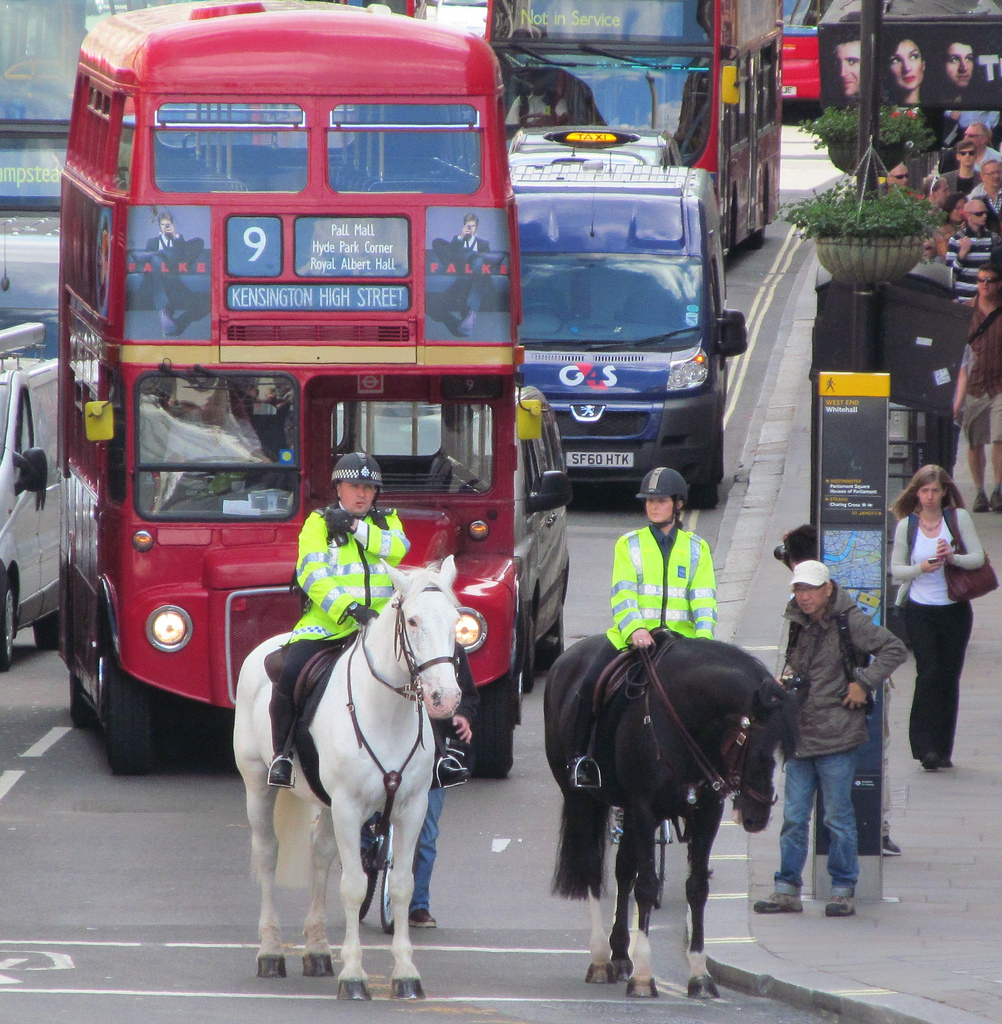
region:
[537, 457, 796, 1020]
A policewoman riding a horse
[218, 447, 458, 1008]
A policeman riding a horse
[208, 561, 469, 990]
A white horse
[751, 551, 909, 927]
A man standing on the street corner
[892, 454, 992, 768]
A woman walking down the sidewalk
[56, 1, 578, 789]
A red double decker bus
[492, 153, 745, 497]
A blue passenger van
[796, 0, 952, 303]
Two hanging plants in baskets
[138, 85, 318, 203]
window on a bus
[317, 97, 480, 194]
window on a bus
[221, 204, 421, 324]
sign on a bus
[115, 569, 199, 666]
light on a bus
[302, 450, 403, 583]
man wearing a helmet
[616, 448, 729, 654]
woman wearing a helmet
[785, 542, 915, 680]
man wearing a hat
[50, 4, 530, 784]
A large red commuter bus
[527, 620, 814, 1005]
Beautiful healthy horse used for the British police department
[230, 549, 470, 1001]
Beautiful healthy white horse used for the British police department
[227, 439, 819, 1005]
British police mounted on horses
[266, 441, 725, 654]
British police officers wear bright colored and reflective vests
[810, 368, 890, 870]
Posts with maps of the city are placed at corners for visitors and tourists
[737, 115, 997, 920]
Commuters walk around the city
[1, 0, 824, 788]
automobiles are use for some to commute around the city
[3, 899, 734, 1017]
white lines across the road are use by pedestrians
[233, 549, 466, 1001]
A white police horse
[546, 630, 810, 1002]
Black police horse on the street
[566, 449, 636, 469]
License plate of a blue car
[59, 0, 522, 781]
Red double decker bus on the street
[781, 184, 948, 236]
Green plant in a pot hanging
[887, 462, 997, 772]
Woman carrying a purse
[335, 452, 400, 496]
Person wearing black helmet.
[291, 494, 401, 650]
Person wearing bright green coat.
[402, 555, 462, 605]
Horse has white mane.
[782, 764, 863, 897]
Person wearing blue jeans.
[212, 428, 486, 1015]
a police on a horse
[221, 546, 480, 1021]
the horse is white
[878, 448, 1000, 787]
woman holds a purse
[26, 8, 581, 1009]
a double decker bus on back a police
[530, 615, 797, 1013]
the horse is black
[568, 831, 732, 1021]
the legs are white and black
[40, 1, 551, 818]
A red double decker bus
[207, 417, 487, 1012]
A man riding a white horse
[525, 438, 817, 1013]
A person on a black horse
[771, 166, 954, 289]
A green plant in a basket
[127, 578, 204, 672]
A round headlight is on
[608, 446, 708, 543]
Black helmet on person's head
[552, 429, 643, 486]
A white license plate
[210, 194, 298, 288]
Number 9 on a bus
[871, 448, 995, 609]
A woman wearing a white long sleeved shirt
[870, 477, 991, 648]
a person on the sidewalk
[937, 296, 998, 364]
a person on the sidewalk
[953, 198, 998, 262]
a person on the sidewalk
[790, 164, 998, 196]
a person on the sidewalk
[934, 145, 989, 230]
a person on the sidewalk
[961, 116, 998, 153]
a person on the sidewalk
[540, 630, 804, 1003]
a black horse with white ankles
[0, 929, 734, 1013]
white lines on the road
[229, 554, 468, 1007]
a white horse with gray hooves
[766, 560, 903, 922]
a man wearing blue jeans and a white cap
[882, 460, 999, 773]
a woman wearing black pants